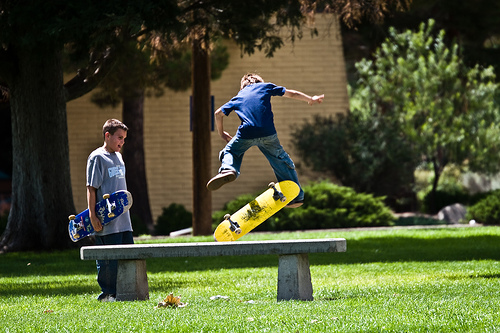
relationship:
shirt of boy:
[216, 82, 290, 140] [199, 68, 346, 210]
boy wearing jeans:
[199, 68, 346, 210] [219, 133, 313, 199]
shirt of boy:
[75, 145, 146, 232] [76, 117, 153, 304]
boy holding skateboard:
[76, 117, 153, 304] [63, 186, 135, 242]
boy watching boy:
[76, 117, 153, 304] [199, 68, 346, 210]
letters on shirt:
[104, 163, 130, 178] [75, 145, 146, 232]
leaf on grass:
[153, 289, 182, 314] [1, 227, 500, 332]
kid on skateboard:
[199, 68, 346, 210] [209, 176, 306, 244]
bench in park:
[75, 235, 358, 302] [0, 205, 500, 333]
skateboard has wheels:
[209, 176, 306, 244] [264, 177, 297, 209]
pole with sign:
[190, 5, 215, 234] [210, 94, 217, 130]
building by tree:
[61, 4, 359, 213] [3, 4, 178, 240]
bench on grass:
[75, 235, 358, 302] [1, 227, 500, 332]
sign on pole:
[210, 94, 217, 130] [190, 5, 215, 234]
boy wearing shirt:
[199, 68, 346, 210] [216, 82, 290, 140]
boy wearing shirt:
[76, 117, 153, 304] [75, 145, 146, 232]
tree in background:
[3, 4, 178, 240] [0, 4, 499, 160]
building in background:
[61, 4, 359, 213] [0, 4, 499, 160]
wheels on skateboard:
[102, 191, 119, 222] [63, 186, 135, 242]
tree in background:
[371, 23, 495, 210] [0, 4, 499, 160]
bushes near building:
[227, 182, 386, 229] [61, 4, 359, 213]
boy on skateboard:
[199, 68, 346, 210] [209, 176, 306, 244]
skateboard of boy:
[209, 176, 306, 244] [199, 68, 346, 210]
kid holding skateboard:
[76, 117, 153, 304] [63, 186, 135, 242]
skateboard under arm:
[63, 186, 135, 242] [80, 169, 109, 236]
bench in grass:
[75, 235, 358, 302] [1, 227, 500, 332]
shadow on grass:
[10, 249, 86, 272] [1, 227, 500, 332]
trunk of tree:
[10, 44, 76, 245] [3, 4, 178, 240]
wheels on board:
[264, 177, 297, 209] [209, 176, 306, 244]